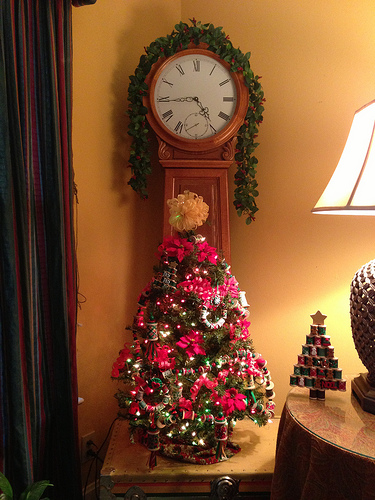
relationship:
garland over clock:
[132, 19, 256, 59] [145, 40, 247, 261]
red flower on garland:
[183, 25, 189, 33] [132, 19, 256, 59]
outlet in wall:
[80, 430, 98, 464] [71, 0, 189, 490]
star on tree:
[310, 311, 327, 326] [288, 309, 346, 401]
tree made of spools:
[288, 309, 346, 401] [339, 379, 347, 391]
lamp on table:
[311, 96, 374, 414] [270, 373, 371, 499]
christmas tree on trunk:
[114, 190, 274, 466] [98, 412, 282, 498]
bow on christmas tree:
[166, 188, 211, 232] [114, 190, 274, 466]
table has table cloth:
[270, 373, 371, 499] [276, 373, 375, 497]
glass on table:
[288, 372, 374, 459] [270, 373, 371, 499]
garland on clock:
[132, 19, 256, 59] [145, 40, 247, 261]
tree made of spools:
[288, 309, 346, 401] [289, 374, 299, 386]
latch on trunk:
[208, 477, 241, 500] [98, 412, 282, 498]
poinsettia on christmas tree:
[158, 236, 196, 261] [114, 190, 274, 466]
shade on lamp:
[310, 95, 374, 216] [311, 96, 374, 414]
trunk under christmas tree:
[98, 412, 282, 498] [114, 190, 274, 466]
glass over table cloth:
[288, 372, 374, 459] [276, 373, 375, 497]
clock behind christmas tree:
[145, 40, 247, 261] [114, 190, 274, 466]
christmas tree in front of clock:
[114, 190, 274, 466] [145, 40, 247, 261]